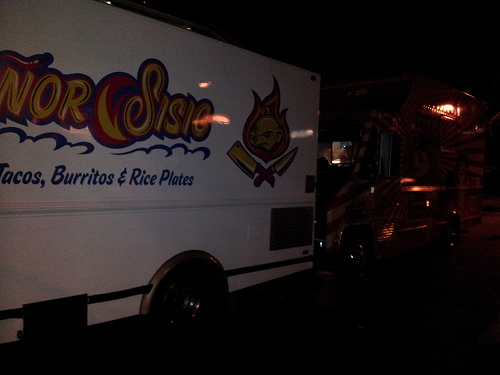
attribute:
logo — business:
[0, 47, 224, 155]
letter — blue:
[186, 173, 196, 187]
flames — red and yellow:
[217, 77, 311, 174]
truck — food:
[5, 4, 443, 349]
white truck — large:
[4, 1, 326, 366]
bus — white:
[0, 58, 345, 355]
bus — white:
[78, 46, 429, 351]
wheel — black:
[144, 259, 231, 374]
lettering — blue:
[0, 161, 195, 186]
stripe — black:
[231, 249, 319, 286]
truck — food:
[0, 4, 325, 351]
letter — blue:
[157, 163, 173, 187]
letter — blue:
[178, 170, 188, 187]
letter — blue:
[169, 173, 181, 185]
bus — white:
[0, 0, 326, 350]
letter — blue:
[43, 159, 118, 189]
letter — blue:
[0, 160, 48, 190]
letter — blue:
[0, 158, 199, 192]